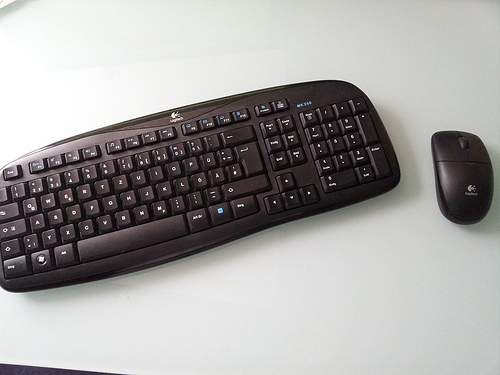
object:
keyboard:
[0, 79, 400, 293]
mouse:
[430, 130, 494, 226]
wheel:
[457, 136, 469, 149]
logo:
[464, 184, 478, 196]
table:
[0, 0, 499, 375]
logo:
[169, 111, 184, 123]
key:
[207, 201, 233, 227]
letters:
[296, 103, 300, 107]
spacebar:
[75, 213, 192, 262]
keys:
[206, 167, 228, 187]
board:
[227, 77, 366, 96]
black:
[457, 168, 483, 181]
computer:
[0, 0, 15, 9]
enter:
[240, 146, 249, 153]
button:
[233, 141, 264, 178]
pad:
[297, 97, 394, 195]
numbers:
[327, 123, 332, 127]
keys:
[299, 183, 320, 205]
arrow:
[288, 195, 295, 200]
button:
[230, 195, 260, 219]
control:
[236, 203, 245, 208]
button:
[186, 208, 211, 235]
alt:
[192, 214, 203, 220]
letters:
[100, 184, 106, 189]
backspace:
[226, 135, 233, 140]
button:
[219, 126, 256, 149]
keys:
[321, 121, 343, 139]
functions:
[85, 149, 96, 156]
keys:
[157, 126, 177, 142]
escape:
[6, 171, 13, 175]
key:
[3, 164, 23, 181]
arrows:
[284, 179, 289, 183]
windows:
[38, 256, 45, 262]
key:
[31, 249, 57, 273]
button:
[432, 130, 469, 162]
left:
[431, 130, 469, 226]